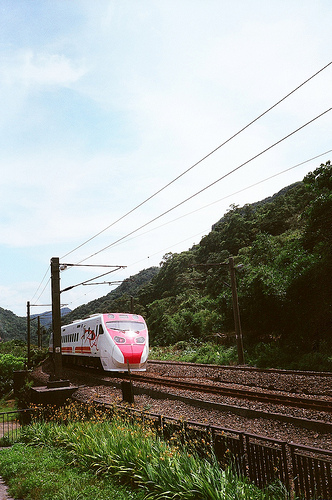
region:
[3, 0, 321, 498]
Exterior shot, daytime, rural view.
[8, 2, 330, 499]
Modern vehicle, in outdoor, country setting with vegetation, probably, during summer.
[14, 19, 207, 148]
Pale blue sky, with fluffy clouds.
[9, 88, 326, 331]
Wooden posts with electrical wires.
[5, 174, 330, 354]
Far and near mountain ranges with green vegetation.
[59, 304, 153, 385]
Approaching, passenger train.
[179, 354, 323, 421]
Rusty, brown rails with gravel between ties.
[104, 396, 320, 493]
Low, metal fencing.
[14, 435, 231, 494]
High plants and grasses, alongside fencing.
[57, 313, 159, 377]
White body with red details and facing, on train.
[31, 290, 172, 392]
the train is white in colour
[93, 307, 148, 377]
its red on the front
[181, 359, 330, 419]
the rail is brown in colour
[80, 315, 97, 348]
the doors are closed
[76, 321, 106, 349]
its decorated on the side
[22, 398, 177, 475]
the flowers are brown in colour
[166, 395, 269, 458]
the rail is marbeled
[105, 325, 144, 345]
the lights are off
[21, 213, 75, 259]
the sky has clouds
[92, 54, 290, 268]
power lines over train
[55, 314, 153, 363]
red and white train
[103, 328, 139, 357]
red lights on train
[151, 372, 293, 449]
train on brown tracks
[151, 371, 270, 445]
brown gravel near tracks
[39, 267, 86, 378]
wood poles near train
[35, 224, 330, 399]
green trees beside track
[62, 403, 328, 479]
black fence near track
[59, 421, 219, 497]
green leaves by fence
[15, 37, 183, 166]
sky is blue and white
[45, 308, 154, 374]
RED AND WHITE PASSENGER RAIL TRAIN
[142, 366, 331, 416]
TRACK FOR THE RAIL TRAIN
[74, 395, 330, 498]
FENCE ALONG SIDE THE RAIL WAY TRACK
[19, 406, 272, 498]
LUSH GREEN GRASS AGAINST FENCE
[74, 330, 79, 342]
PASSENGER WINDOW OF RAIL TRAIN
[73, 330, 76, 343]
PASSENGER WINDOW OF RAIL TRAIN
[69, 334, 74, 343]
PASSENGER WINDOW OF RAIL TRAIN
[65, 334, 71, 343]
PASSENGER WINDOW OF RAIL TRAIN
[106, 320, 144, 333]
CONDUCTORS WINDOW OF THE RAIL TRAIN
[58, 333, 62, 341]
PASSENGER WINDOW OF RAIL TRAIN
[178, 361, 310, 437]
A rocky railroad track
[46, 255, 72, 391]
A tall electrical pole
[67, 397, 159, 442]
Orange flowers along the railroad tracks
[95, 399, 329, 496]
A brown fence running along the tracks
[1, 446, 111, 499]
A patch of tall green grass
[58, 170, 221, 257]
A series of long electrical wire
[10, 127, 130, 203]
A sky with clouds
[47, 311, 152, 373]
A red and white train on the tracks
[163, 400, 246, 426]
A bunch of gravel on the railroad tracks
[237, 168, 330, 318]
A large hill with many trees